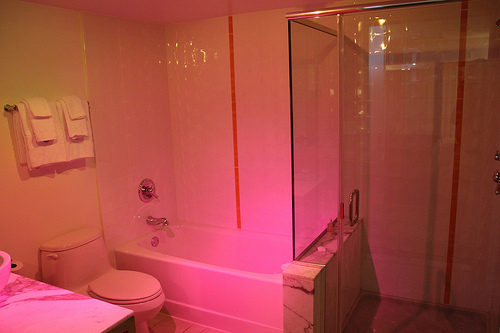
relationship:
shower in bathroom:
[91, 18, 307, 291] [38, 24, 495, 328]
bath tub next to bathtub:
[115, 225, 284, 332] [128, 220, 310, 278]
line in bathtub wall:
[228, 13, 241, 228] [166, 7, 303, 228]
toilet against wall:
[46, 218, 172, 318] [0, 5, 93, 241]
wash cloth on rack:
[22, 97, 53, 117] [1, 96, 93, 114]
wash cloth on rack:
[59, 94, 86, 119] [1, 96, 93, 114]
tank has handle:
[29, 200, 123, 293] [33, 247, 62, 263]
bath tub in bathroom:
[115, 225, 284, 332] [108, 220, 289, 330]